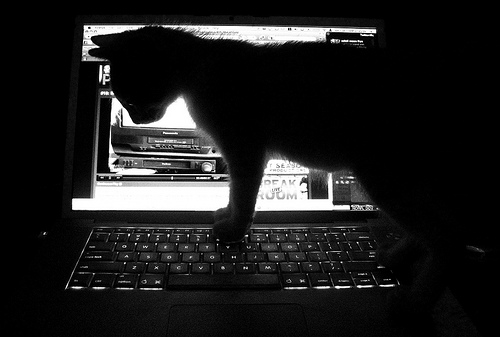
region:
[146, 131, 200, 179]
monitor of a laptop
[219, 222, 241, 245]
part of a left paw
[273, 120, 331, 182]
stomach of a cat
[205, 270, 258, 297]
part of a backspace button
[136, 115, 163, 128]
mouth of a cat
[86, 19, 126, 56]
left ear of a cat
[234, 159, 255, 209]
part of a leg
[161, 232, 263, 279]
top of keyboard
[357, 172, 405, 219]
hind leg of a cat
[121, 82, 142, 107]
eye of a cat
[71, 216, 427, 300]
backlit keyboard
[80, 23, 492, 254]
cat in the dark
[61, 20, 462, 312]
laptop turned on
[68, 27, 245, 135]
cat's head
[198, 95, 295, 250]
cat's legs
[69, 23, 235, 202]
well lit screen shining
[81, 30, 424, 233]
cat shrouded in darkness illuminated by laptop light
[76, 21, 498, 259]
cat looking down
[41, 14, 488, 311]
laptop shining into the dark room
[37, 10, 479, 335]
cat climbing on turned on laptop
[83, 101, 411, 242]
screen is bright and illuminated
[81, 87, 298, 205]
screen is bright and illuminated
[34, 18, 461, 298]
A black and white photo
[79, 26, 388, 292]
A black and white photo of a cat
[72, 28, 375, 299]
A cat on a laptop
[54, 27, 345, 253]
A cat on a keyboard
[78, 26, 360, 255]
A cat in front of a lit screen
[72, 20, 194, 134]
The head of a cat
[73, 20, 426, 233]
A cat from the side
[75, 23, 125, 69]
The ears of a cat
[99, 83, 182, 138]
The nose of a cat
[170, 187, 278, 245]
The paws of a cat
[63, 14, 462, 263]
cat is using keyboard